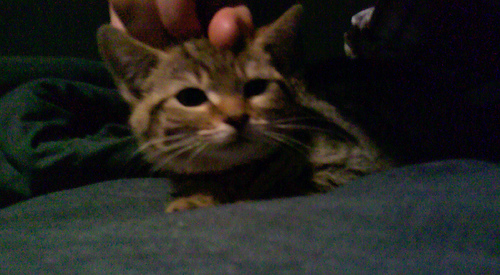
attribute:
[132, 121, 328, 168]
whiskers — gray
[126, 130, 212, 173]
whiskers — white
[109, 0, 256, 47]
person — white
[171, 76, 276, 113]
eyes — black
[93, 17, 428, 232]
cat — black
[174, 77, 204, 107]
eye — dark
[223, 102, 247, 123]
nose — tan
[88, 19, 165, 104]
ear — tan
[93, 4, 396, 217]
cat — brown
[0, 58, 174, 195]
green fabric — folded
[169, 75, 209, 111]
eye — dark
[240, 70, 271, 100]
eye — dark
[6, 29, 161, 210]
blanket — green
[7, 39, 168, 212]
blanket — green